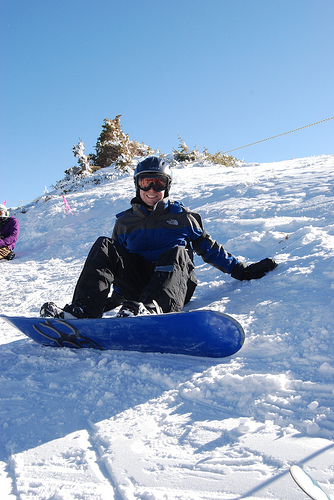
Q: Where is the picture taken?
A: On a hill.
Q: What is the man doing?
A: Snowboarding.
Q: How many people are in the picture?
A: Two.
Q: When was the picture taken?
A: Daytime.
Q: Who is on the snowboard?
A: A man.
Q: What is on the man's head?
A: Helmet.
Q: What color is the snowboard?
A: Blue.